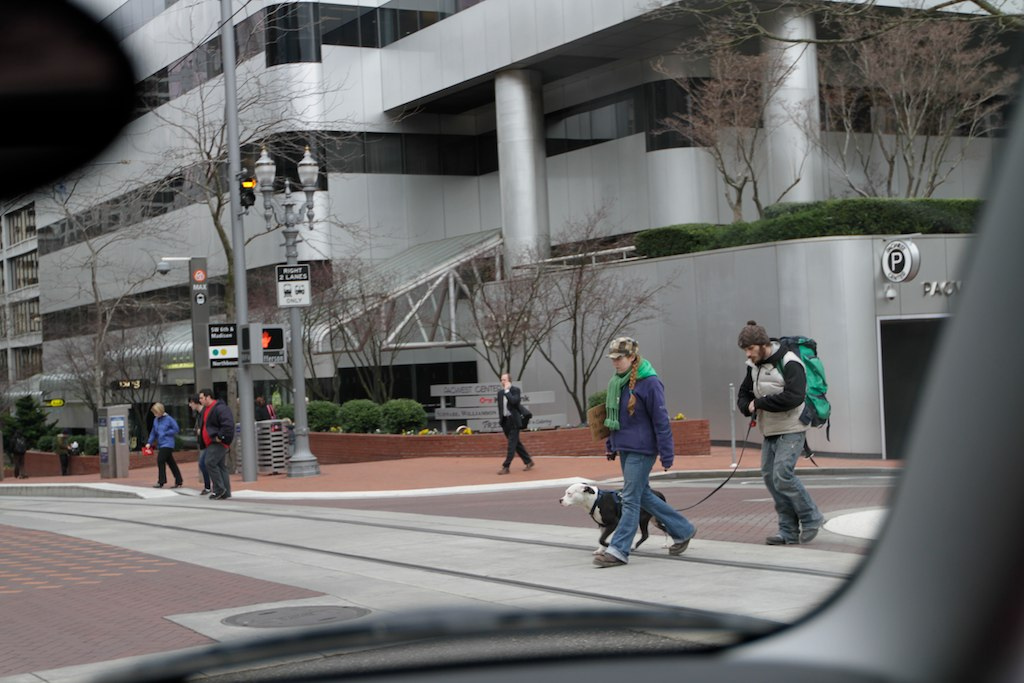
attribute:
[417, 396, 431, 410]
leaves — green